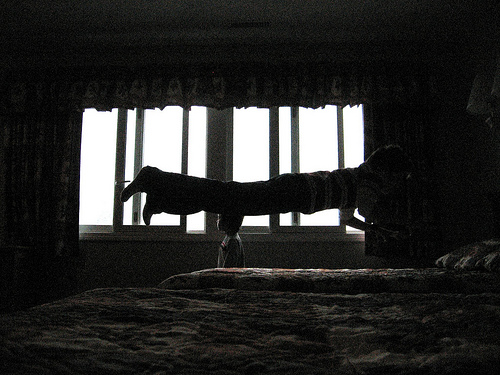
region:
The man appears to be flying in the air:
[117, 140, 422, 240]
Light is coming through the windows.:
[77, 106, 368, 229]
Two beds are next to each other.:
[2, 248, 499, 373]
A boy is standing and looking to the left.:
[216, 212, 244, 265]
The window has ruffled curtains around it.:
[2, 65, 439, 261]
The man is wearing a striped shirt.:
[288, 165, 386, 222]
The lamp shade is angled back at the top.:
[465, 66, 497, 117]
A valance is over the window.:
[0, 66, 451, 111]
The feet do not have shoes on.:
[120, 165, 161, 225]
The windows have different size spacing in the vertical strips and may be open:
[81, 106, 366, 229]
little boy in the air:
[116, 133, 439, 255]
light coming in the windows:
[75, 107, 352, 232]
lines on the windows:
[107, 105, 367, 226]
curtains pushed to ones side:
[1, 97, 107, 269]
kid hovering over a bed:
[98, 125, 499, 287]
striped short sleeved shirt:
[299, 156, 390, 227]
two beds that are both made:
[0, 233, 497, 374]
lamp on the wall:
[457, 69, 497, 131]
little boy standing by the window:
[210, 206, 247, 264]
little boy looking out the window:
[172, 161, 278, 273]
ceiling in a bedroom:
[0, 2, 491, 44]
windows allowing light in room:
[78, 106, 360, 240]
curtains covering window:
[1, 71, 492, 257]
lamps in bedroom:
[467, 75, 495, 132]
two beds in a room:
[0, 238, 498, 373]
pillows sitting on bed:
[435, 238, 499, 270]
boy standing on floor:
[212, 209, 245, 274]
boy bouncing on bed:
[119, 140, 411, 236]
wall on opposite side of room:
[0, 241, 364, 311]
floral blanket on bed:
[0, 288, 490, 373]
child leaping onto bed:
[102, 127, 422, 250]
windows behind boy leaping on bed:
[62, 95, 374, 247]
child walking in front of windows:
[209, 208, 261, 268]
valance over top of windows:
[12, 65, 431, 103]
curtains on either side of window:
[9, 108, 455, 250]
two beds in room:
[32, 221, 487, 374]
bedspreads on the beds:
[47, 241, 499, 361]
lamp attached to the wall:
[460, 67, 498, 134]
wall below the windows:
[75, 240, 364, 290]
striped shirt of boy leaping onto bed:
[290, 157, 387, 234]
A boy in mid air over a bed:
[118, 144, 415, 240]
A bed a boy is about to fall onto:
[0, 282, 499, 372]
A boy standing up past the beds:
[216, 212, 245, 269]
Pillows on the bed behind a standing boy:
[435, 238, 499, 280]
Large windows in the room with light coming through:
[81, 103, 366, 236]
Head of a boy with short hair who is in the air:
[364, 140, 412, 187]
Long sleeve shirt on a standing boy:
[216, 234, 244, 269]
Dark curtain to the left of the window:
[1, 72, 82, 293]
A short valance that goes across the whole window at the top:
[3, 66, 444, 111]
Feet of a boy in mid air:
[120, 163, 157, 226]